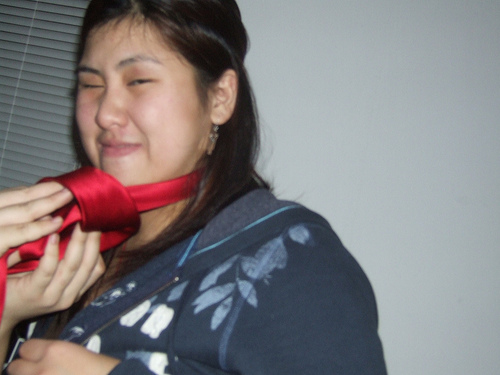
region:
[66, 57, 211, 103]
almond-shaped eyes on woman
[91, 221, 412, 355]
zippered hooded blue jacket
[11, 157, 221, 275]
red silky tie being tied around neck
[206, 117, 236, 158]
silver pierced earrings on woman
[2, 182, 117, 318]
woman's hands tying tie on Asian woman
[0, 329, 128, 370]
Asian woman's left hand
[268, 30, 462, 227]
blank white wall behind woman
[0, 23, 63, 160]
one-inch mini blinds behind woman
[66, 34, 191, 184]
Asian woman's face, smiling somewhat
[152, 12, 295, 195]
Asian woman's black hair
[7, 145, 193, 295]
the red tie the woman is wearing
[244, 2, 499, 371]
the wall next to the woman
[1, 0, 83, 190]
the blinds covering the woman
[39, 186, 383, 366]
the jacket the woman is wearing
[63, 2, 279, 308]
the woman's long black hair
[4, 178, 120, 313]
the hands holding the tie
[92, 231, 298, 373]
the illustration on the jacket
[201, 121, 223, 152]
the earring in the woman's ear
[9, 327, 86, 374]
the woman's hand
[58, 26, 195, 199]
the woman's face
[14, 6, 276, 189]
a woman with black hair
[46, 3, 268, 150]
a woman with her eyes half closed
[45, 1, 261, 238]
a woman with a red tie around her neck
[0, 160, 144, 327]
a person tying a tie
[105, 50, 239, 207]
a woman wearing a ear ring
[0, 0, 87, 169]
a white mini blind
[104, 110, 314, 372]
a woman wearing a blue jacket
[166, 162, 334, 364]
a blue jacket with a floral print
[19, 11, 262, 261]
a woman with long hair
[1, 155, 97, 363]
a persons hands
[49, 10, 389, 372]
an asian women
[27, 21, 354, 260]
a woman with black hair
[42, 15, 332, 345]
a woman with hair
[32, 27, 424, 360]
a woman wearing a tie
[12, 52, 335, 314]
a woman wearing a red tie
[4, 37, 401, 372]
a woman wearing a jacket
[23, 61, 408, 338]
a woman with blue jacket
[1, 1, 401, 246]
a woman wearing earrings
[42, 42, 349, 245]
wearing tie and earrings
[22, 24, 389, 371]
woman with hair up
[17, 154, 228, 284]
red tie is around girl's neck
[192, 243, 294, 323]
white flowers are on blue sweatshirt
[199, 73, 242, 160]
earring is hanging from girl's ear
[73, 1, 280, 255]
girl has dark hair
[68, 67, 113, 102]
girl has one closed eye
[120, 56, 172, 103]
girl has one open eye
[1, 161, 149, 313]
two hands are looping necktie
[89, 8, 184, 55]
girl has wispy bangs on her forehead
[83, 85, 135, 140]
big nose on girl's face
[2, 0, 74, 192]
beige window blinds are closed